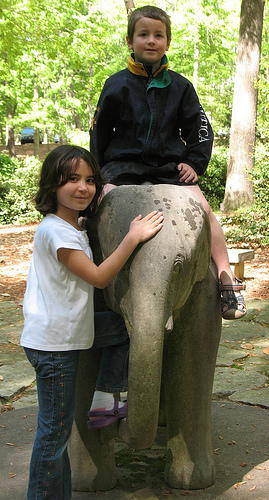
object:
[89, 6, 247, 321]
boy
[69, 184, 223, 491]
elephant statue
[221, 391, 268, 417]
stone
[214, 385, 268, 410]
cracks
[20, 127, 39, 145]
car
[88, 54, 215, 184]
coat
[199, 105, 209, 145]
letters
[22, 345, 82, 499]
jeans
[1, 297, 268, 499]
shadows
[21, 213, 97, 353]
shirt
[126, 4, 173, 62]
head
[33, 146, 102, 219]
head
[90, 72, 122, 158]
arm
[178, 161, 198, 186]
hand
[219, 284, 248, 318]
foot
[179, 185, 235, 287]
left leg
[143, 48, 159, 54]
mouth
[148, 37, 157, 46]
nose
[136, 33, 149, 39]
right eye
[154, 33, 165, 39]
left eye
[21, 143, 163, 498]
children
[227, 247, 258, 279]
bench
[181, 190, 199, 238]
dirt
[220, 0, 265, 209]
tree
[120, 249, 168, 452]
trunk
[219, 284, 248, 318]
left shoe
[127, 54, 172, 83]
collar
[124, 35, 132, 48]
right ear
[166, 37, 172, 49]
left ear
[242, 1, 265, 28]
bark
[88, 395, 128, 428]
sandles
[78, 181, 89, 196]
nose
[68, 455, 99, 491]
hoofs